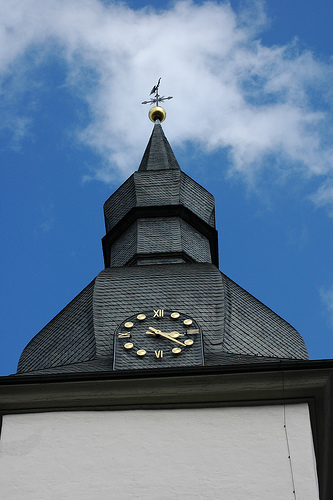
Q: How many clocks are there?
A: 1.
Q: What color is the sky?
A: Blue.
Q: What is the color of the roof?
A: Black.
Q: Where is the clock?
A: On the rooftop.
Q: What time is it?
A: 3:23.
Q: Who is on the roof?
A: Nobody.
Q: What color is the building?
A: White.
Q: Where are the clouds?
A: In the sky.